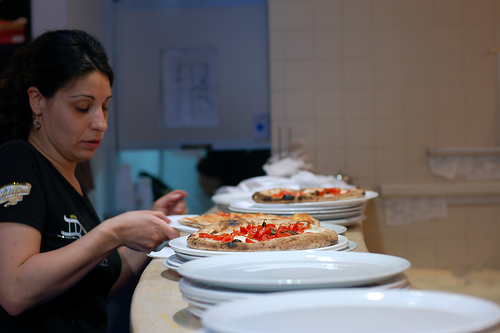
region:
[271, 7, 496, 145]
white wall tile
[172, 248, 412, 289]
a large white plate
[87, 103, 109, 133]
the nose of a woman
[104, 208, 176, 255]
the hand of a woman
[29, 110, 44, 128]
a woman's earring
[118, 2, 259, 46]
part of a white wall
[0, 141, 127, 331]
part of a woman's black shirt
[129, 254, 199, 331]
part of a counter top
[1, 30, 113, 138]
a woman's black hair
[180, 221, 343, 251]
a large pizza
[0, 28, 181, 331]
A woman in black t-shirt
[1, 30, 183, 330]
Woman holding a plate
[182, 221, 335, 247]
Pizza on white plate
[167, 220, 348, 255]
White plate with pizza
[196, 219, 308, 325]
Tomato pieces on pizza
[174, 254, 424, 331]
White plates piled on top of each other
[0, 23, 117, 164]
A woman closing eyes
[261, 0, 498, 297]
Beige tiles on wall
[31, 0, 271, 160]
Blue part of wall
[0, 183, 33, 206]
Logo on black t-shirt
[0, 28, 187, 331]
Waitress grabbing a plate of food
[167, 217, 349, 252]
Small fresh baked pizza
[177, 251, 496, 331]
Two stacks of white plates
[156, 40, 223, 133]
Laminated paper on a cabinet door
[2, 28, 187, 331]
Woman wearing a black shirt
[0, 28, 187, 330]
Woman closing her eyes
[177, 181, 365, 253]
Three fresh baked pizzas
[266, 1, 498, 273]
White tiled wall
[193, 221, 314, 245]
Tomato toppings on a pizza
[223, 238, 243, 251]
Black burnt pizza crust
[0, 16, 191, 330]
woman in a black t-shirt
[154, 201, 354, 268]
pizza on a white plate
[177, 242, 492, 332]
stacks of white plates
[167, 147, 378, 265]
pizza on white plates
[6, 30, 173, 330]
woman with black hair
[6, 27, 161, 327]
restaurant server getting a pizza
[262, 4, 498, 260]
white tile wall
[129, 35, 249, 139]
paper posted on a cabinet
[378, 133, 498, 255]
restaurant orders on a wall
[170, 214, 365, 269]
pizza with tomatoes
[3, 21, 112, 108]
She has dark hair.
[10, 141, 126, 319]
His shirt is black.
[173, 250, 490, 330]
The plates are white.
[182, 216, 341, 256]
The pizza is on the plate.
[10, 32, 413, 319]
The girl is taking the pizza.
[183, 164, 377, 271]
The pizza are on the counter.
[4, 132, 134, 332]
Her shirt is black.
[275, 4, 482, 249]
The wall is tan.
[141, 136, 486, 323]
The plates are on the counter.